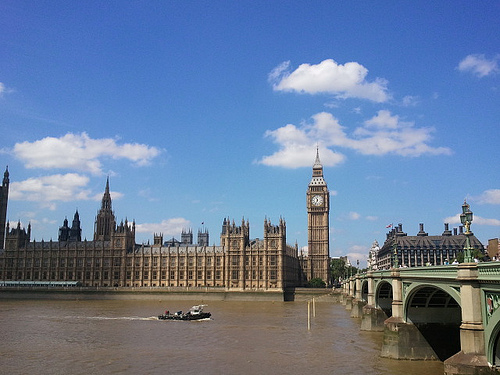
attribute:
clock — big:
[313, 197, 324, 207]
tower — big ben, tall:
[306, 145, 331, 288]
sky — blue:
[1, 1, 499, 270]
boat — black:
[157, 306, 210, 321]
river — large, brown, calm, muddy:
[1, 298, 460, 375]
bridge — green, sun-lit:
[340, 264, 500, 373]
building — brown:
[1, 218, 304, 289]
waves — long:
[64, 317, 157, 323]